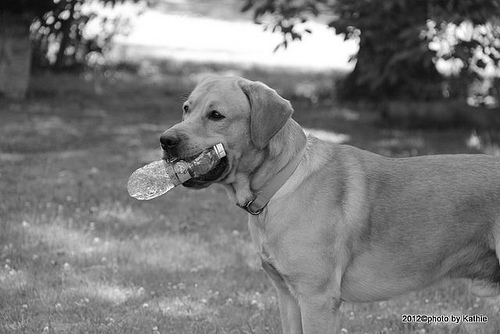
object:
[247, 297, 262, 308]
mark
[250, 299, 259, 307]
mark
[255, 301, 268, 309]
mark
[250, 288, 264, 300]
mark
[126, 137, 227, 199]
bottle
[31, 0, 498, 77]
road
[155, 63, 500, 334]
dog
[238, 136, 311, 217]
collar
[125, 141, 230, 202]
bottle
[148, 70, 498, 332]
lab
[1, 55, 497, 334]
grass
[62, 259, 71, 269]
flower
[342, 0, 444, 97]
trunk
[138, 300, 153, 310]
mark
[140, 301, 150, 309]
mark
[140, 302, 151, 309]
mark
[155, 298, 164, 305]
mark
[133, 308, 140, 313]
mark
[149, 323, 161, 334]
mark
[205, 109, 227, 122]
eye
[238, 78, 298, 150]
ear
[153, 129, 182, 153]
nose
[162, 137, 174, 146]
snout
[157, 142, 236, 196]
mouth